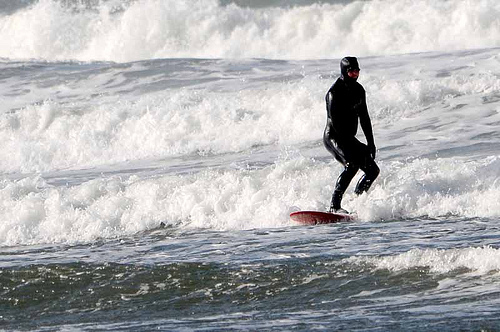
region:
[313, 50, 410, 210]
person in full wet suit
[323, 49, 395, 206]
person in black full body wet suit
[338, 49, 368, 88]
person wearing a wet suit hood and goggles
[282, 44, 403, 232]
person on a surfboard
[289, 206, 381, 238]
red surfboard riding the waves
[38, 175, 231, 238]
white caps on top of the waves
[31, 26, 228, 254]
waves rolling into the beach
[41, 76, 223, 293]
waves with white caps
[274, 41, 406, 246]
surf boarder coming into the beach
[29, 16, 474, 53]
large wave rolling in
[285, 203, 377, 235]
red surfboard in the water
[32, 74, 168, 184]
waves with white foam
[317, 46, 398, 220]
man in a black wetsuit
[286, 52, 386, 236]
man standing on a surfboard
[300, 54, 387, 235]
man surfing in ocean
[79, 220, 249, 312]
grey ocean water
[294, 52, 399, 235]
man wearing wetsuit and standing on surfboard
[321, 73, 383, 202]
shiny black wetsuit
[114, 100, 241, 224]
white seafoam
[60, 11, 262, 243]
three waves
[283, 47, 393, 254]
A man surfing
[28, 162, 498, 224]
a wave crashing down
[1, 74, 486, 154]
a wave crashing down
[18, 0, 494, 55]
a wave crashing down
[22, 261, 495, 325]
A wave building up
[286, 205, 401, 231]
A red surf board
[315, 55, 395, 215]
A black wetsuit on the man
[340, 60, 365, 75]
goggles on the man's head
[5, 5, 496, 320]
The ocean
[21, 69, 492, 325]
sea foam in the water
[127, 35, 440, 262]
person surfing some waves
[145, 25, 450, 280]
person surfing some nice waves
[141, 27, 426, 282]
person surfing some awesome waves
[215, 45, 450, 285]
person surfing some ocean waves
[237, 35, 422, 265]
person surfing some beautiful waves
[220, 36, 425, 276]
person surfing some great waves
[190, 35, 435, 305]
person surfing nice ocean waves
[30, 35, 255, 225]
some really nice ocean waves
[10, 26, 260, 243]
some beautiful ocean waves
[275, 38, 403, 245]
person surfing in dark suit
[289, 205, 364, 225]
a red snowboard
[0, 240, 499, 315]
waves with white caps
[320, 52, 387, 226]
a man wearing a black wet suit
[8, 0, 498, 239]
a bunch of surf waves in water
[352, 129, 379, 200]
a man surfing has one leg up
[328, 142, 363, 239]
a man surfing with left leg on board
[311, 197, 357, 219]
surfer wearing white tennis shoes on surf board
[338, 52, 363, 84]
man wearing hat while surfing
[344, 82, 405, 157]
man is holding right leg with one arm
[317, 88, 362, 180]
left arm is holding left leg